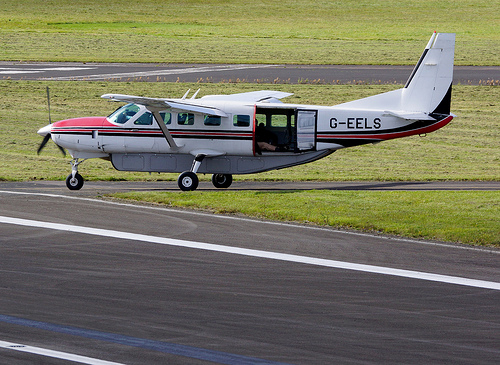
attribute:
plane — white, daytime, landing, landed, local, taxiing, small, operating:
[38, 24, 468, 185]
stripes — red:
[33, 111, 450, 138]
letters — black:
[305, 102, 396, 138]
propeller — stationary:
[30, 56, 58, 164]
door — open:
[237, 100, 305, 159]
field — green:
[19, 86, 40, 185]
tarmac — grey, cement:
[20, 207, 462, 364]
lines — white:
[7, 175, 486, 302]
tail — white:
[393, 31, 460, 151]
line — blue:
[8, 317, 173, 363]